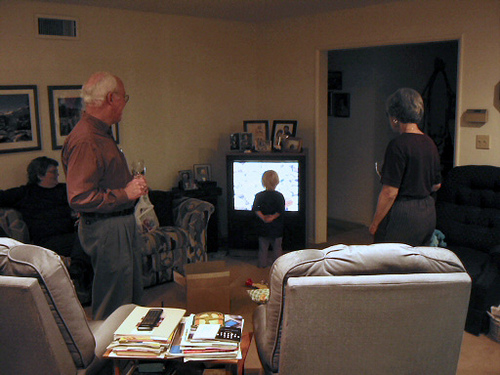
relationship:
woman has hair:
[370, 85, 443, 246] [385, 85, 426, 123]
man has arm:
[59, 69, 149, 320] [63, 140, 128, 212]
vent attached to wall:
[35, 13, 80, 40] [0, 0, 253, 238]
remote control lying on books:
[137, 308, 163, 332] [104, 304, 186, 358]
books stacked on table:
[110, 304, 244, 363] [103, 328, 254, 374]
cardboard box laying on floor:
[173, 256, 241, 312] [77, 228, 498, 374]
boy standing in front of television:
[250, 168, 286, 271] [225, 151, 307, 252]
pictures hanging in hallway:
[326, 69, 351, 120] [327, 47, 373, 241]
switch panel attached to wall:
[473, 132, 491, 152] [254, 0, 498, 244]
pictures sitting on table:
[175, 161, 210, 189] [175, 179, 223, 252]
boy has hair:
[250, 168, 286, 271] [260, 169, 282, 190]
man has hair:
[59, 69, 149, 320] [79, 68, 116, 107]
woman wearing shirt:
[370, 85, 443, 246] [381, 132, 442, 197]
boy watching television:
[250, 168, 286, 271] [225, 151, 307, 252]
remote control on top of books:
[137, 308, 163, 332] [104, 304, 186, 358]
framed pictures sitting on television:
[227, 118, 302, 152] [225, 151, 307, 252]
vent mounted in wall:
[35, 13, 80, 40] [0, 0, 253, 238]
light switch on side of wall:
[481, 138, 485, 145] [254, 0, 498, 244]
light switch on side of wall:
[476, 137, 483, 146] [254, 0, 498, 244]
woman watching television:
[370, 85, 443, 246] [225, 151, 307, 252]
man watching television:
[59, 69, 149, 320] [225, 151, 307, 252]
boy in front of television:
[250, 168, 286, 271] [225, 151, 307, 252]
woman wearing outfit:
[370, 85, 443, 246] [373, 130, 441, 246]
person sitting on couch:
[0, 154, 94, 306] [0, 182, 215, 304]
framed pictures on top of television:
[227, 118, 302, 152] [225, 151, 307, 252]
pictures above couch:
[175, 161, 210, 189] [0, 182, 215, 304]